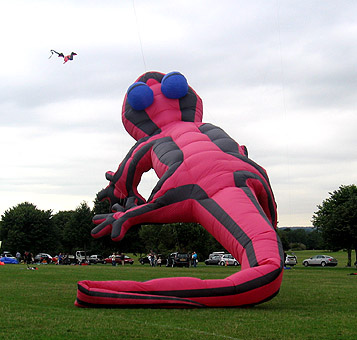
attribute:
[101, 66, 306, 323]
balloon — red, black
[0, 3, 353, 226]
sky — cloudy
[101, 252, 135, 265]
car — red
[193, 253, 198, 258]
shirt — blue 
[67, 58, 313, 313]
lizard balloon — large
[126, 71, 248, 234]
body — pink , black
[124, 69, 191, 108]
blue eyes — Blue 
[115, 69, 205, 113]
eye — blue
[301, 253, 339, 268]
car — gray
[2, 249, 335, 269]
cars — many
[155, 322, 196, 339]
cable — gray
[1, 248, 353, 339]
grass — green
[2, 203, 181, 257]
trees — dark green 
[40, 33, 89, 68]
kite — balloon 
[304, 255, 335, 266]
sedan — silver 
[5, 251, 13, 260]
tarp — blue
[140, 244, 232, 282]
suv — black, large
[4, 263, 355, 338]
grass — green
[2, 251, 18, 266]
object — blue 